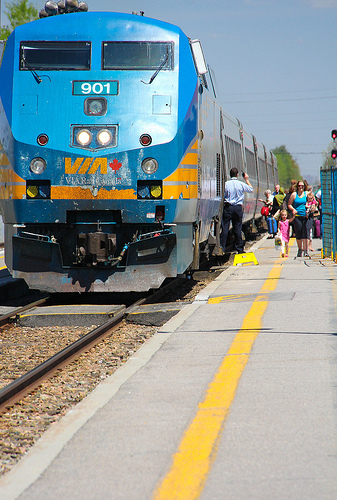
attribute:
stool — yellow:
[233, 251, 258, 268]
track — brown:
[1, 291, 152, 408]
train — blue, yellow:
[2, 13, 278, 294]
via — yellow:
[63, 155, 109, 178]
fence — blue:
[319, 166, 336, 263]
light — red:
[330, 129, 336, 135]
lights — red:
[331, 127, 336, 162]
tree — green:
[274, 149, 297, 183]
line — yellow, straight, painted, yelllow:
[155, 256, 286, 498]